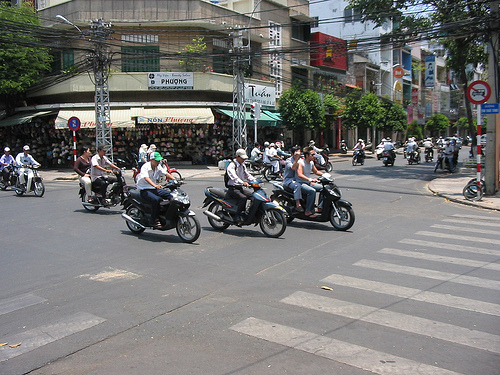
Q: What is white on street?
A: Broad white lines.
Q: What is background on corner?
A: Large brown building.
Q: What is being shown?
A: A motorcycle ride.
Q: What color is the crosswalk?
A: White.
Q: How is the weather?
A: Sunny.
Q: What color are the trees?
A: Green.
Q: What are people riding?
A: Motorcycles.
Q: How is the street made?
A: Of concrete.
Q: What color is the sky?
A: Blue.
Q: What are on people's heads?
A: Caps.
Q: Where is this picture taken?
A: An intersection.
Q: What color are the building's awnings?
A: Cream and green.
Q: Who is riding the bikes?
A: People.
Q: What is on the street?
A: Bikes.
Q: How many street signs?
A: 2.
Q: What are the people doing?
A: Riding.